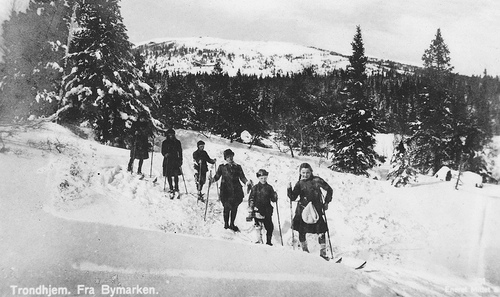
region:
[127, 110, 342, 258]
Skiing children in snow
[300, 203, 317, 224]
Hat hanging from girl's coat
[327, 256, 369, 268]
Points of little girl's skis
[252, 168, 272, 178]
Hat on little boy's head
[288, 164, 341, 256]
Little girl at front of skier line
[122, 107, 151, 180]
Little girl at back of skier line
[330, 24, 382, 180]
Cone shaped pine tree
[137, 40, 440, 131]
Mountain with snow on top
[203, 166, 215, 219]
Ski pole in person's hand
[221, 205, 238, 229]
Legs of skier on slope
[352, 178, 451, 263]
The snow is the color white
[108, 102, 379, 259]
A group of people in the snow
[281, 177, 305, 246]
The woman is holding a ski stick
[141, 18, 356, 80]
The mountain is covered in snow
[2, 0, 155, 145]
The tree is very tall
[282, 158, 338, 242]
The woman is wearing a dress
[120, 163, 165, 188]
The person has on skis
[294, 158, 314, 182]
The head of the woman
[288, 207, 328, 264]
The legs of the woman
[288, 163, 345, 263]
a cross country skier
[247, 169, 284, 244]
a cross country skier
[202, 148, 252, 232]
a cross country skier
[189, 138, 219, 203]
a cross country skier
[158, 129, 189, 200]
a cross country skier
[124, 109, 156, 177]
a cross country skier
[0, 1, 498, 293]
a vintage black and white photograph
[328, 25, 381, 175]
large evergreen tree in distance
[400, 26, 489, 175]
large evergreen tree in distance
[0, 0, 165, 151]
large evergreen tree in distance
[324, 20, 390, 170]
tree covered in green leaves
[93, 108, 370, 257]
row of people standing in snow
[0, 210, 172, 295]
ground covered in snow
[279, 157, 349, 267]
person holding metal ski poles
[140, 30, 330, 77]
mountainside covered in snow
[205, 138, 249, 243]
person in dark clothing standing in snow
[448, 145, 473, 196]
small tree with no leaves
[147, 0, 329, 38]
sky full of hazy clouds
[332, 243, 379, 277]
tip of metal skis in snow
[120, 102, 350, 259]
skiers lined up on the mountainside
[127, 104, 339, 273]
skiers holding ski poles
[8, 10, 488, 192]
trees along the mountainside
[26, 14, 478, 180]
trees dusted with snow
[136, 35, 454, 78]
snow covered mountain in the background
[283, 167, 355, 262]
young girl wearing a skirt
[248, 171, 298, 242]
young boy posing for photo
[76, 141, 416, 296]
tracks in the snow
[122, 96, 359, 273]
six skiers posed on the mountainside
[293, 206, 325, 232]
skirt worn by skier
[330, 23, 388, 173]
tall tree along side the ski path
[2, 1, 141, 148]
tall tree along side the ski path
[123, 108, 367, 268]
line of young skiers in the white snow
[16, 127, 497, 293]
ski tracks in the white snow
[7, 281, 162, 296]
white letters in black and white image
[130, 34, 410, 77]
rolling hills covered with white snow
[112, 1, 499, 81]
high sky with complete cloud cover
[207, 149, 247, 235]
person wearing a dark hat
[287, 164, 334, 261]
young girl carrying a white bag on her waist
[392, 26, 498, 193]
tall tree along side the ski path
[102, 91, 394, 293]
the people are posing for a photo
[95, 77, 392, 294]
they are in the mountains